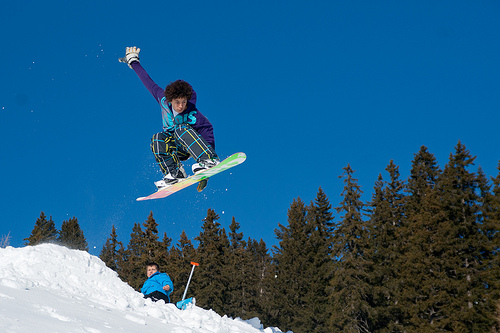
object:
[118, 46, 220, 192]
boy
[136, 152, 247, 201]
snowboard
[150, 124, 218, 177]
pants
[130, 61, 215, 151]
sweatshirt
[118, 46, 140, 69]
glove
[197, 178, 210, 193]
glove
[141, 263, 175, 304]
man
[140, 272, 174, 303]
jacket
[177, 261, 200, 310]
handle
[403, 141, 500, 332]
trees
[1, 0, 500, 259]
sky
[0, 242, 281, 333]
ski slope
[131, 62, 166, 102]
arm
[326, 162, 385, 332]
tree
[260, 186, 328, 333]
tree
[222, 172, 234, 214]
snow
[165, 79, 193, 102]
hair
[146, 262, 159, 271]
hair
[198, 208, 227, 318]
tree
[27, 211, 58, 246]
tree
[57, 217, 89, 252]
tree